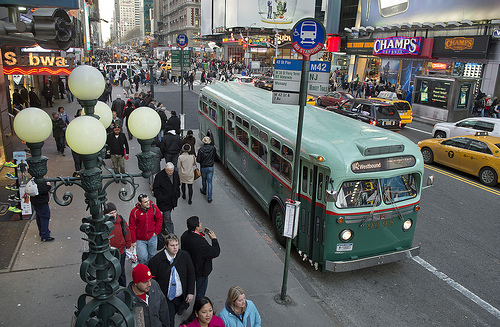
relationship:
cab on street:
[417, 128, 497, 181] [421, 161, 491, 216]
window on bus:
[332, 171, 424, 210] [196, 80, 434, 273]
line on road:
[410, 250, 497, 322] [130, 69, 496, 324]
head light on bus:
[338, 230, 354, 240] [193, 70, 440, 277]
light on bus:
[398, 216, 415, 240] [193, 70, 440, 277]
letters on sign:
[375, 39, 416, 51] [373, 38, 423, 54]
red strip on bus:
[191, 90, 425, 219] [193, 70, 440, 277]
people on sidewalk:
[52, 49, 499, 325] [21, 248, 66, 313]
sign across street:
[373, 36, 424, 57] [306, 282, 498, 316]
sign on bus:
[355, 157, 415, 173] [193, 70, 440, 277]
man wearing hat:
[119, 263, 191, 320] [119, 261, 158, 283]